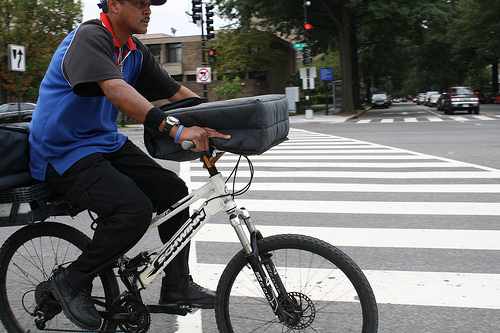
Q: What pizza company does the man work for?
A: Dominos.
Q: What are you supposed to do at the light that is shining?
A: Stop.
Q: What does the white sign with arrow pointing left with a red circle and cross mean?
A: No left turn.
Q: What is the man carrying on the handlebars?
A: Pizza temperature bag.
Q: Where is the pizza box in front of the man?
A: Handle bars.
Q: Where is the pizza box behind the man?
A: Basket above rear tire.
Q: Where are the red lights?
A: On street lights.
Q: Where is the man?
A: On the bike.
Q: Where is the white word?
A: On the bike.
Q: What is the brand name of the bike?
A: Schwinn.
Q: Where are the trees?
A: To man's left.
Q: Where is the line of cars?
A: Under trees.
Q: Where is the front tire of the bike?
A: In crosswalk.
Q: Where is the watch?
A: Man's left wrist.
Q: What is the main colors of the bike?
A: Black and white.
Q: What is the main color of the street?
A: Grey.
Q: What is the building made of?
A: Brick.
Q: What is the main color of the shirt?
A: Blue.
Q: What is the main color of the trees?
A: Green.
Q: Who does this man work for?
A: Pizza place.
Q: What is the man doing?
A: Delivering a pizza.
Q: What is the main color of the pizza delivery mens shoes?
A: Black.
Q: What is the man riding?
A: A bicycle.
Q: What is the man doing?
A: Delivering food.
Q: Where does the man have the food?
A: In the black pouches.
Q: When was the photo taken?
A: Daytime.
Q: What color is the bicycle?
A: White.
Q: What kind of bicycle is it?
A: Schwinn.